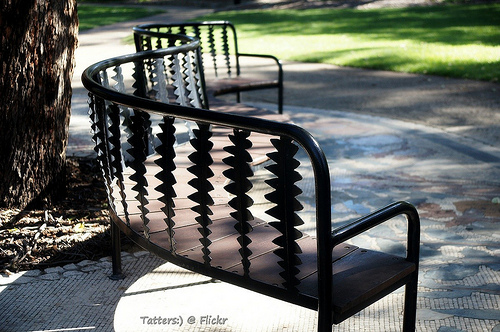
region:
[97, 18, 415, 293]
this bench is curved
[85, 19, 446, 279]
the bench is metal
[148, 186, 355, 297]
the seating is wood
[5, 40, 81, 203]
a trunk on the tree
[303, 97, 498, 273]
stone pavers on the ground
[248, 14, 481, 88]
green grass in the area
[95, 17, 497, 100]
the sun is shining on the ground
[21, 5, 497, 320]
this bench is in an outdoor area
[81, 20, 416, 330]
the bench is curved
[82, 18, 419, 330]
the bench is black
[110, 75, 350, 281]
sunlight on the bench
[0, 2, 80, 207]
tree near the bench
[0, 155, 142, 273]
a circle of dirt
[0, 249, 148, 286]
cobble stones near tree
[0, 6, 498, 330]
walkway in the park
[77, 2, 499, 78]
some areas of grass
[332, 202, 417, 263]
handle of the bench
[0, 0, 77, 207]
the bark is brown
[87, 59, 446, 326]
bench that is outside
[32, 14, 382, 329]
a bench by a tree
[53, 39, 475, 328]
a long bench outside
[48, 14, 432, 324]
a bench on the sidewalk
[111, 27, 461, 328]
a long bench by the tree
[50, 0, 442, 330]
a metal bench outside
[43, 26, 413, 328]
a metal bench by a tree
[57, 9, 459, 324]
a metal bench on a sidewalk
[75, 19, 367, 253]
a long metal bench outside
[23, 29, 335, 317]
a long metal bench on the tree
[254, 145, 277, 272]
There is a bench that is visible here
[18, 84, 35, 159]
There is a large tree that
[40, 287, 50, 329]
There is an off-white sidewalk here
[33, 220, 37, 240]
There are twigs around the tree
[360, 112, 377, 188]
There jeweled areas here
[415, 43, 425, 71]
There is a patch of green grass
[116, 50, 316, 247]
This photo looks very detailed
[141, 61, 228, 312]
This photo has a wonderful perspective